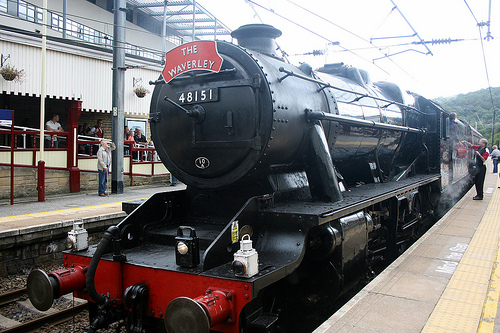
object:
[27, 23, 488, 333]
train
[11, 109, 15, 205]
pole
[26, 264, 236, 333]
bumper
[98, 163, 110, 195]
jeans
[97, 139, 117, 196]
man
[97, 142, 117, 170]
jacket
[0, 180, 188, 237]
stripe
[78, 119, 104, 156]
person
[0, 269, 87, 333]
track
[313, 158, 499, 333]
pavement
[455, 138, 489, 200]
man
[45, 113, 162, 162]
people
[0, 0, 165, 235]
platform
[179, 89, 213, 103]
number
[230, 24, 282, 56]
chimney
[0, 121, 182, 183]
ramp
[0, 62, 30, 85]
plant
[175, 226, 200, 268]
light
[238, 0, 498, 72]
wires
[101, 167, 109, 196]
cane